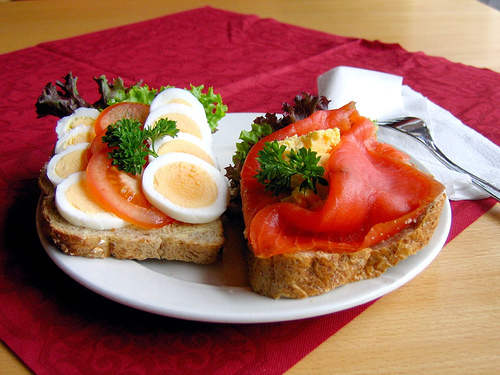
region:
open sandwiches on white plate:
[32, 21, 469, 346]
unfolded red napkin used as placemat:
[10, 0, 475, 360]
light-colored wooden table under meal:
[340, 0, 485, 60]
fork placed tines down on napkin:
[345, 60, 490, 195]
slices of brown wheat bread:
[30, 216, 445, 292]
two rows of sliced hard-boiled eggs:
[40, 90, 220, 260]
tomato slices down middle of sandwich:
[95, 70, 160, 225]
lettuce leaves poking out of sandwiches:
[35, 65, 330, 140]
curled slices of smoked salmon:
[235, 100, 440, 250]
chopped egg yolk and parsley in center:
[255, 122, 340, 192]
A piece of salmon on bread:
[220, 83, 447, 266]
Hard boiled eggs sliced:
[153, 87, 221, 229]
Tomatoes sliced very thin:
[89, 97, 160, 226]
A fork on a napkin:
[386, 70, 498, 215]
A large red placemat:
[117, 0, 310, 95]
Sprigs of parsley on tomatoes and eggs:
[96, 105, 164, 172]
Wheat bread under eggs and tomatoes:
[49, 212, 219, 262]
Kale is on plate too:
[28, 76, 148, 108]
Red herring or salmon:
[328, 180, 414, 236]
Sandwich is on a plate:
[108, 213, 334, 345]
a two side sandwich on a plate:
[25, 83, 450, 327]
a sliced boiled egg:
[143, 76, 210, 228]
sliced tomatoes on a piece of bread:
[89, 97, 147, 237]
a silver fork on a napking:
[378, 102, 453, 159]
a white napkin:
[357, 69, 474, 171]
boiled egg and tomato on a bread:
[46, 67, 230, 269]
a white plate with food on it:
[10, 92, 478, 363]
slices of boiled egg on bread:
[151, 79, 216, 256]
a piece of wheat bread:
[246, 188, 453, 307]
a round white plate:
[55, 125, 450, 326]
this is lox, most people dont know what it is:
[235, 102, 445, 262]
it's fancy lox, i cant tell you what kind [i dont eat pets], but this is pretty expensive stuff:
[237, 100, 437, 260]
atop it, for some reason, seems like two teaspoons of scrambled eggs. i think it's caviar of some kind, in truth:
[261, 120, 342, 175]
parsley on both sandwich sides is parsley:
[100, 115, 332, 205]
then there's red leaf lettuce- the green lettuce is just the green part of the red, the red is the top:
[35, 70, 335, 200]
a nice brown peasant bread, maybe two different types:
[31, 100, 451, 310]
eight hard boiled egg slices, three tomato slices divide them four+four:
[47, 85, 217, 240]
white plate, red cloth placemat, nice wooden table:
[0, 5, 495, 370]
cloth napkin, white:
[310, 60, 495, 250]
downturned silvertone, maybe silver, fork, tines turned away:
[365, 105, 498, 220]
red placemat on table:
[3, 5, 498, 369]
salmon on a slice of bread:
[242, 98, 446, 302]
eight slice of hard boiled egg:
[41, 86, 224, 266]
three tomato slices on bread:
[37, 87, 232, 264]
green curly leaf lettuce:
[38, 66, 223, 128]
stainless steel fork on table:
[375, 111, 499, 198]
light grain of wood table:
[277, 203, 497, 373]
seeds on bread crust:
[46, 220, 108, 259]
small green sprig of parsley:
[250, 139, 329, 198]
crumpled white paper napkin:
[317, 58, 499, 211]